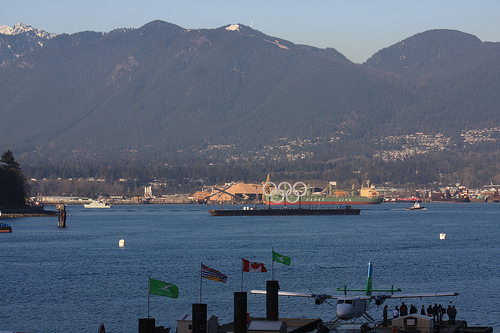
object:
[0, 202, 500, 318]
water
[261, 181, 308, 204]
logo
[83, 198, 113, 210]
motor boat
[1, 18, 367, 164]
mountain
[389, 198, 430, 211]
boat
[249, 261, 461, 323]
airplane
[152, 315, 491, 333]
pontoons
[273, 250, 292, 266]
flag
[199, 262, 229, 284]
flag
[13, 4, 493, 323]
air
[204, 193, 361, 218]
boat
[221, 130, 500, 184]
ground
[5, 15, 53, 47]
peak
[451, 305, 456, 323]
passengers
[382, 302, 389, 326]
passengers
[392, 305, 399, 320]
passengers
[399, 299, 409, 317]
passengers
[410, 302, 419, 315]
passengers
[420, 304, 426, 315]
passengers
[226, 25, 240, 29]
snow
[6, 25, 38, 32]
snow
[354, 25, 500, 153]
mountain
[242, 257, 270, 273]
flag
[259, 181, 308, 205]
olympic rings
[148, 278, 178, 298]
flag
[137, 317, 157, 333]
post